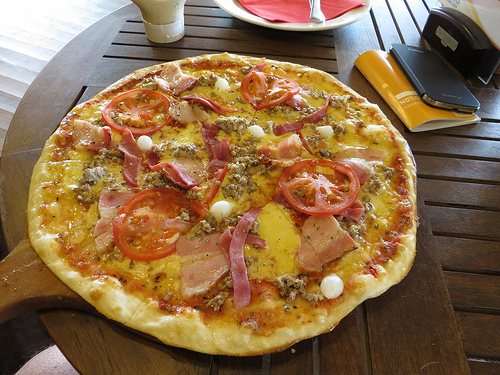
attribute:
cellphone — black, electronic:
[390, 39, 481, 114]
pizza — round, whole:
[27, 49, 421, 354]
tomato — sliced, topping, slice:
[276, 155, 362, 217]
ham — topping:
[228, 201, 261, 309]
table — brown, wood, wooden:
[0, 2, 497, 372]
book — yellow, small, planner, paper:
[353, 48, 480, 131]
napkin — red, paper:
[238, 1, 366, 23]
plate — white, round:
[212, 0, 372, 32]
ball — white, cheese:
[315, 275, 346, 300]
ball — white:
[135, 134, 155, 150]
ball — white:
[210, 199, 233, 220]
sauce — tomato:
[374, 153, 413, 262]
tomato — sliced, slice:
[112, 184, 209, 258]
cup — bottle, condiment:
[128, 1, 187, 43]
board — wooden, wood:
[1, 237, 96, 320]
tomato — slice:
[99, 85, 177, 134]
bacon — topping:
[272, 92, 336, 133]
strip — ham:
[118, 126, 143, 186]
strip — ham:
[146, 146, 193, 187]